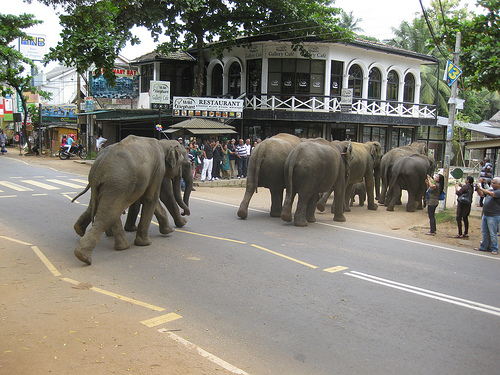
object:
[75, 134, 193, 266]
elephant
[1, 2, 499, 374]
photo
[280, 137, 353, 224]
elephant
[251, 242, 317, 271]
line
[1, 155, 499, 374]
street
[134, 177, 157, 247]
leg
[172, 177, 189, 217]
trunk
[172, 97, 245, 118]
sign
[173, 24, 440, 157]
building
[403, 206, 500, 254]
dirt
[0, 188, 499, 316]
ground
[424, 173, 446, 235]
person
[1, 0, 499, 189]
background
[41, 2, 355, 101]
tree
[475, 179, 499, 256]
person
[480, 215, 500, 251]
jeans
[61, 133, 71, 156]
woman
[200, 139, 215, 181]
man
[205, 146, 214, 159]
shirt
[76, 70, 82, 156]
pole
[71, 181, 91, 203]
tail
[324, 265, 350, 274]
line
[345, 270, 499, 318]
lines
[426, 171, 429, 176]
phone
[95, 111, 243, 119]
awning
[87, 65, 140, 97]
poster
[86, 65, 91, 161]
pole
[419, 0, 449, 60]
lines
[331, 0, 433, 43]
sky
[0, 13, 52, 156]
tree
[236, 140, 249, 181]
person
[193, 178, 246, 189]
sidewalk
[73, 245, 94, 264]
foot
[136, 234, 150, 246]
foot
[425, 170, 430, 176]
picture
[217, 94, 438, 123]
railing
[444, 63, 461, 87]
sign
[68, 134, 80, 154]
person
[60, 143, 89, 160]
motorcycle